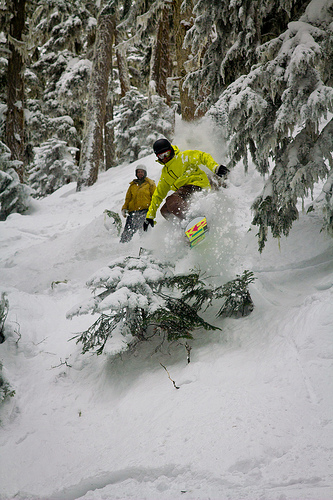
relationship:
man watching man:
[139, 138, 236, 220] [121, 164, 152, 243]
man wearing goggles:
[143, 138, 231, 235] [154, 147, 176, 161]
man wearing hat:
[117, 150, 164, 232] [130, 153, 153, 182]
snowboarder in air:
[143, 136, 234, 242] [163, 214, 245, 268]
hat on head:
[153, 137, 174, 162] [152, 139, 174, 162]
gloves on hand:
[216, 162, 225, 180] [135, 214, 157, 235]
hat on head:
[129, 162, 152, 173] [134, 162, 148, 180]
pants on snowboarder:
[159, 183, 201, 228] [143, 137, 229, 248]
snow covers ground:
[258, 245, 306, 282] [263, 235, 315, 294]